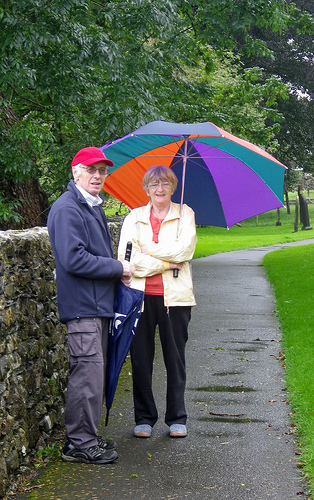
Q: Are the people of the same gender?
A: No, they are both male and female.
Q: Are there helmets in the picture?
A: No, there are no helmets.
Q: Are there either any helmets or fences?
A: No, there are no helmets or fences.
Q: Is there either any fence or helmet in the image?
A: No, there are no helmets or fences.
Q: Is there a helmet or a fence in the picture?
A: No, there are no helmets or fences.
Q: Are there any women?
A: Yes, there is a woman.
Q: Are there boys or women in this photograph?
A: Yes, there is a woman.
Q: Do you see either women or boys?
A: Yes, there is a woman.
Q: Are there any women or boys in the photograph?
A: Yes, there is a woman.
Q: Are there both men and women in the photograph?
A: Yes, there are both a woman and a man.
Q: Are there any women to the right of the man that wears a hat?
A: Yes, there is a woman to the right of the man.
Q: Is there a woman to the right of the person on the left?
A: Yes, there is a woman to the right of the man.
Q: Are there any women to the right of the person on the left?
A: Yes, there is a woman to the right of the man.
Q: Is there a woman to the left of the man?
A: No, the woman is to the right of the man.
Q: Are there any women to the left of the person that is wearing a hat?
A: No, the woman is to the right of the man.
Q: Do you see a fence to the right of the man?
A: No, there is a woman to the right of the man.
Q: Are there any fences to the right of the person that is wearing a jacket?
A: No, there is a woman to the right of the man.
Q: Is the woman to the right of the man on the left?
A: Yes, the woman is to the right of the man.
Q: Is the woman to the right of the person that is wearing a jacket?
A: Yes, the woman is to the right of the man.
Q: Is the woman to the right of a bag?
A: No, the woman is to the right of the man.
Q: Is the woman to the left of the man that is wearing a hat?
A: No, the woman is to the right of the man.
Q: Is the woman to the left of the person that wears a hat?
A: No, the woman is to the right of the man.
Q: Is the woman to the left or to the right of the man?
A: The woman is to the right of the man.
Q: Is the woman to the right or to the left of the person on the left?
A: The woman is to the right of the man.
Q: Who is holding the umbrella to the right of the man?
A: The woman is holding the umbrella.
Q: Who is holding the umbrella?
A: The woman is holding the umbrella.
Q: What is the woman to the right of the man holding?
A: The woman is holding the umbrella.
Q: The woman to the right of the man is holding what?
A: The woman is holding the umbrella.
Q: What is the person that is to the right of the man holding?
A: The woman is holding the umbrella.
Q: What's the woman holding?
A: The woman is holding the umbrella.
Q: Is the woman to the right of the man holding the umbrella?
A: Yes, the woman is holding the umbrella.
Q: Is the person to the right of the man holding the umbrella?
A: Yes, the woman is holding the umbrella.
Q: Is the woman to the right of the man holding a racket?
A: No, the woman is holding the umbrella.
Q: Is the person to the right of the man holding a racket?
A: No, the woman is holding the umbrella.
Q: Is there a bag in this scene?
A: No, there are no bags.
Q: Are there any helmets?
A: No, there are no helmets.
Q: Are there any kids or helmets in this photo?
A: No, there are no helmets or kids.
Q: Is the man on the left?
A: Yes, the man is on the left of the image.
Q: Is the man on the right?
A: No, the man is on the left of the image.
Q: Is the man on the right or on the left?
A: The man is on the left of the image.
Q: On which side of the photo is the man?
A: The man is on the left of the image.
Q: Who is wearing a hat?
A: The man is wearing a hat.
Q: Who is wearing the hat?
A: The man is wearing a hat.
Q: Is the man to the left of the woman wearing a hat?
A: Yes, the man is wearing a hat.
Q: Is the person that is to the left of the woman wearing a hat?
A: Yes, the man is wearing a hat.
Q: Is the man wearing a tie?
A: No, the man is wearing a hat.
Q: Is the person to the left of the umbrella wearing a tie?
A: No, the man is wearing a hat.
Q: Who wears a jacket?
A: The man wears a jacket.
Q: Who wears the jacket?
A: The man wears a jacket.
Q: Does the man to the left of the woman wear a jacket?
A: Yes, the man wears a jacket.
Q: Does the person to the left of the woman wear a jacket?
A: Yes, the man wears a jacket.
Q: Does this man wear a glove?
A: No, the man wears a jacket.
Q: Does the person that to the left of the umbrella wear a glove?
A: No, the man wears a jacket.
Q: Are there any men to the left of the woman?
A: Yes, there is a man to the left of the woman.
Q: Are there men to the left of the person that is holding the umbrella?
A: Yes, there is a man to the left of the woman.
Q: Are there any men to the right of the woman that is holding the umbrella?
A: No, the man is to the left of the woman.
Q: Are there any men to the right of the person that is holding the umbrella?
A: No, the man is to the left of the woman.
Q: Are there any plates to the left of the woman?
A: No, there is a man to the left of the woman.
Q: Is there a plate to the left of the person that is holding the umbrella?
A: No, there is a man to the left of the woman.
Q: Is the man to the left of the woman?
A: Yes, the man is to the left of the woman.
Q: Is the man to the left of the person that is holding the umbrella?
A: Yes, the man is to the left of the woman.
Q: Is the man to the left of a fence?
A: No, the man is to the left of the woman.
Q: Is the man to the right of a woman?
A: No, the man is to the left of a woman.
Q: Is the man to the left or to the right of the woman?
A: The man is to the left of the woman.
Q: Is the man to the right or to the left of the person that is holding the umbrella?
A: The man is to the left of the woman.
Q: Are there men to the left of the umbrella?
A: Yes, there is a man to the left of the umbrella.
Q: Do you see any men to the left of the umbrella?
A: Yes, there is a man to the left of the umbrella.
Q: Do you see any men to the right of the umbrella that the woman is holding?
A: No, the man is to the left of the umbrella.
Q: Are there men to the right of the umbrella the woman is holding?
A: No, the man is to the left of the umbrella.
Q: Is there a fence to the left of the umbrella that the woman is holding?
A: No, there is a man to the left of the umbrella.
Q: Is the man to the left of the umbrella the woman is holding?
A: Yes, the man is to the left of the umbrella.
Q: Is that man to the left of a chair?
A: No, the man is to the left of the umbrella.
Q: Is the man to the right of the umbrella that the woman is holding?
A: No, the man is to the left of the umbrella.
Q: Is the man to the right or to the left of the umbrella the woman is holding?
A: The man is to the left of the umbrella.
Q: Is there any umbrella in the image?
A: Yes, there is an umbrella.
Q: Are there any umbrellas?
A: Yes, there is an umbrella.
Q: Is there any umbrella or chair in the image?
A: Yes, there is an umbrella.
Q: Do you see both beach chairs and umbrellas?
A: No, there is an umbrella but no beach chairs.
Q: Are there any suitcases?
A: No, there are no suitcases.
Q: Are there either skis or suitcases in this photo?
A: No, there are no suitcases or skis.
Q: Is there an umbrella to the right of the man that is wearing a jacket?
A: Yes, there is an umbrella to the right of the man.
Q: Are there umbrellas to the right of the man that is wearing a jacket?
A: Yes, there is an umbrella to the right of the man.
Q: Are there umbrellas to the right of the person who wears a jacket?
A: Yes, there is an umbrella to the right of the man.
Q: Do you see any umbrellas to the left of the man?
A: No, the umbrella is to the right of the man.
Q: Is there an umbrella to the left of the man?
A: No, the umbrella is to the right of the man.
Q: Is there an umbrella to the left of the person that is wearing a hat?
A: No, the umbrella is to the right of the man.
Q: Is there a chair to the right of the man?
A: No, there is an umbrella to the right of the man.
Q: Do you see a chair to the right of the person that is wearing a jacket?
A: No, there is an umbrella to the right of the man.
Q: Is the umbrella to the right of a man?
A: Yes, the umbrella is to the right of a man.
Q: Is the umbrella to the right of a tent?
A: No, the umbrella is to the right of a man.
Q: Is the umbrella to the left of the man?
A: No, the umbrella is to the right of the man.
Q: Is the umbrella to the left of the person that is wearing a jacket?
A: No, the umbrella is to the right of the man.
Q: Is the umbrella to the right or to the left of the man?
A: The umbrella is to the right of the man.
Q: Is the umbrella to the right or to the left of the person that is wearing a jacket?
A: The umbrella is to the right of the man.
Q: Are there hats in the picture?
A: Yes, there is a hat.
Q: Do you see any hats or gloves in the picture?
A: Yes, there is a hat.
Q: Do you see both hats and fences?
A: No, there is a hat but no fences.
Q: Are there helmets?
A: No, there are no helmets.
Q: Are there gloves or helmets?
A: No, there are no helmets or gloves.